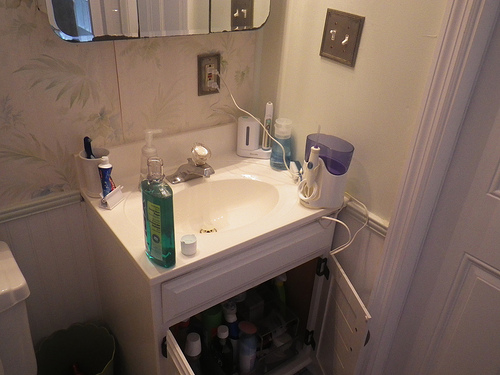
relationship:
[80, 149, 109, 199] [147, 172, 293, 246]
cup on sink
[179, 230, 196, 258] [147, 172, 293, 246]
cap on sink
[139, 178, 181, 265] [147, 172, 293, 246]
mouthwash on sink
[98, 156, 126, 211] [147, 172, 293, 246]
toothpaste on sink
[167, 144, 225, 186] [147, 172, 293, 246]
faucet to sink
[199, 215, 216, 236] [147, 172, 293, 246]
drain in sink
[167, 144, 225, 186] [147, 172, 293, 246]
faucet on sink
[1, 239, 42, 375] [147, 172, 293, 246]
toilet next to sink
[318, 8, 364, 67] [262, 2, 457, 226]
light switch on wall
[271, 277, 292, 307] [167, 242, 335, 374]
cleaner in cabinet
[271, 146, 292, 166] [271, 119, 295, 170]
liquid in bottle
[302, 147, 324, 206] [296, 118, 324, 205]
handle to toothbrush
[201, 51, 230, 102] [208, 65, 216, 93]
outlet has plugs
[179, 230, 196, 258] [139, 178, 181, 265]
cap to mouthwash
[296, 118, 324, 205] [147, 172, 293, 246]
toothbrush on sink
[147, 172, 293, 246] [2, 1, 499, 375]
sink in bathroom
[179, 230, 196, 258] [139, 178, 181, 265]
cap next to mouthwash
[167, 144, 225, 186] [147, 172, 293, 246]
faucet of sink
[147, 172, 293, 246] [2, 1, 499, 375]
sink in a bathroom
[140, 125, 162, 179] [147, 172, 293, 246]
soap dispenser on sink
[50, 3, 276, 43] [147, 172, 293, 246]
mirror above sink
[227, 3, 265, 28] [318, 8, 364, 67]
reflection of light switch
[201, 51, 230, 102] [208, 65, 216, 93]
outlet has two plugs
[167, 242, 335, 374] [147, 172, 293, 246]
cabinet under sink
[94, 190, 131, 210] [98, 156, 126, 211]
stand for toothpaste